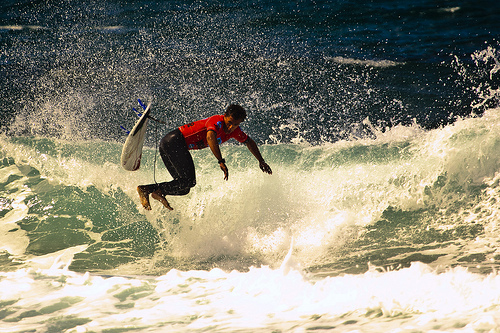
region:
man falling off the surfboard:
[146, 100, 276, 219]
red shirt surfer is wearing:
[176, 110, 242, 147]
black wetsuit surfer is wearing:
[151, 132, 196, 198]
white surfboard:
[115, 95, 163, 172]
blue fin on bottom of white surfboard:
[134, 96, 147, 110]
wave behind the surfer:
[5, 119, 479, 264]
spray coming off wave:
[6, 38, 496, 129]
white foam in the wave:
[8, 148, 490, 318]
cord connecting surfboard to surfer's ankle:
[149, 118, 164, 188]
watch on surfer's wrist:
[215, 158, 229, 165]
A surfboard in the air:
[120, 103, 156, 170]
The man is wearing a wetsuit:
[145, 114, 245, 194]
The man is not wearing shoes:
[137, 184, 169, 209]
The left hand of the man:
[258, 158, 271, 174]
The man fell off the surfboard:
[140, 105, 272, 210]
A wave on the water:
[3, 135, 498, 331]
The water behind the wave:
[0, 0, 499, 140]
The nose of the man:
[228, 123, 232, 128]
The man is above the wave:
[136, 104, 273, 209]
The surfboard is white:
[120, 101, 153, 169]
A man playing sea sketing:
[122, 76, 261, 183]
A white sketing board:
[105, 101, 160, 179]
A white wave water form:
[133, 270, 261, 302]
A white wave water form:
[302, 276, 434, 323]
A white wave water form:
[199, 176, 306, 231]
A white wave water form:
[306, 147, 386, 209]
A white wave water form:
[397, 109, 450, 195]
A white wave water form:
[61, 133, 143, 199]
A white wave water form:
[10, 211, 90, 321]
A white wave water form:
[111, 49, 278, 108]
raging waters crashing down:
[213, 161, 462, 314]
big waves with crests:
[241, 90, 486, 298]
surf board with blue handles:
[111, 75, 161, 177]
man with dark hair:
[120, 57, 282, 252]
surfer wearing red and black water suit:
[141, 41, 273, 242]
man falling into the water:
[97, 29, 283, 249]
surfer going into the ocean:
[85, 56, 292, 260]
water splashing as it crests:
[21, 11, 421, 198]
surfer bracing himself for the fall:
[73, 44, 329, 269]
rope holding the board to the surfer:
[119, 49, 179, 222]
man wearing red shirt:
[164, 88, 267, 165]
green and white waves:
[16, 186, 417, 329]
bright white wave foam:
[172, 254, 297, 321]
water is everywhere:
[161, 32, 459, 303]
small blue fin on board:
[116, 86, 158, 125]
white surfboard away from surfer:
[105, 63, 175, 172]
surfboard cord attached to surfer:
[132, 106, 179, 194]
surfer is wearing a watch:
[203, 144, 242, 184]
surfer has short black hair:
[217, 100, 260, 127]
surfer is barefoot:
[140, 133, 192, 220]